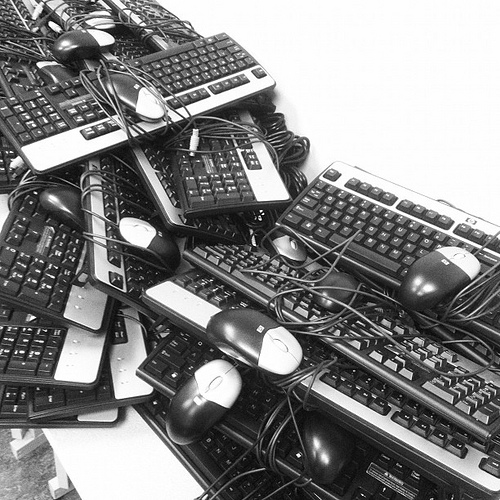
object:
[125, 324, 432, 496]
keyboard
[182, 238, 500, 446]
keyboard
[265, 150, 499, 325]
keyboard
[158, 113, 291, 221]
keyboard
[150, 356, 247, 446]
computer mouse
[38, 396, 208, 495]
table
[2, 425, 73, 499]
floor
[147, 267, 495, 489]
keyboards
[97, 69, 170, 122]
computer mouse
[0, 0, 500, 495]
pile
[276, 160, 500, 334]
computer keyboard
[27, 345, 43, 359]
black keys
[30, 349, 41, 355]
white letters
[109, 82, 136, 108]
lights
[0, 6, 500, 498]
wooden desk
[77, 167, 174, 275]
wires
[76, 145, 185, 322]
computer keyboard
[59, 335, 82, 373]
three lights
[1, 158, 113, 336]
keyboard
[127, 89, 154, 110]
white and grey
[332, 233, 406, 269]
black space key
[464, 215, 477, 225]
hp logo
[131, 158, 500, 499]
bunch of keyboards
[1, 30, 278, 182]
keyboard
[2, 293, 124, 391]
keyboard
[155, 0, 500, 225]
white wall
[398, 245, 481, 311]
two toned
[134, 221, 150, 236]
scrolling button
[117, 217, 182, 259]
computer mouse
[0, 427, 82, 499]
granite pattern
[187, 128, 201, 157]
plug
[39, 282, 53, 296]
buttons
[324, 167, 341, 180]
escape button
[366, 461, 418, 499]
warning sticker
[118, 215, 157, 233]
button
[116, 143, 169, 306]
black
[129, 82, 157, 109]
black and white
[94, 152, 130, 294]
black and white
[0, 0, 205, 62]
black wires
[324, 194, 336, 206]
letter q